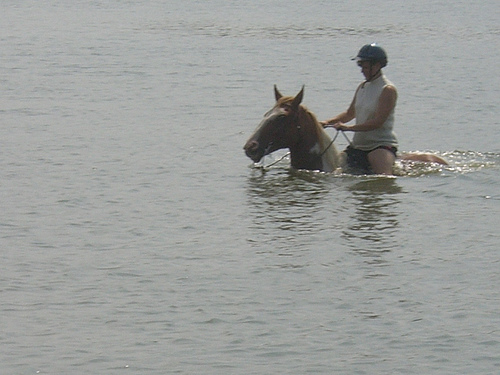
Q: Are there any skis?
A: No, there are no skis.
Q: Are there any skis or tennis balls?
A: No, there are no skis or tennis balls.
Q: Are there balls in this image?
A: No, there are no balls.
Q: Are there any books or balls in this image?
A: No, there are no balls or books.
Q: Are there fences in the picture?
A: No, there are no fences.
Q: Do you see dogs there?
A: No, there are no dogs.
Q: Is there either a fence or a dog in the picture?
A: No, there are no dogs or fences.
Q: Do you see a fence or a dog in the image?
A: No, there are no dogs or fences.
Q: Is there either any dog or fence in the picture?
A: No, there are no dogs or fences.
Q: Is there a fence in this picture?
A: No, there are no fences.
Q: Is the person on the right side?
A: Yes, the person is on the right of the image.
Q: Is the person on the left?
A: No, the person is on the right of the image.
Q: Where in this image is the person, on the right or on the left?
A: The person is on the right of the image.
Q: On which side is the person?
A: The person is on the right of the image.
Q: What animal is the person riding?
A: The person is riding a horse.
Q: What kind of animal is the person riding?
A: The person is riding a horse.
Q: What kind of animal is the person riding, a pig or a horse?
A: The person is riding a horse.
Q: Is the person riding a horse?
A: Yes, the person is riding a horse.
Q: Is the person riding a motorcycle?
A: No, the person is riding a horse.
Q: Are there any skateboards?
A: No, there are no skateboards.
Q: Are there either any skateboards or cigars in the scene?
A: No, there are no skateboards or cigars.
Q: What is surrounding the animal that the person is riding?
A: The water is surrounding the horse.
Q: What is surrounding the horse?
A: The water is surrounding the horse.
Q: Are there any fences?
A: No, there are no fences.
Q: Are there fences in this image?
A: No, there are no fences.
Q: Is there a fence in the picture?
A: No, there are no fences.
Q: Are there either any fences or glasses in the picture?
A: No, there are no fences or glasses.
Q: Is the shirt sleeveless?
A: Yes, the shirt is sleeveless.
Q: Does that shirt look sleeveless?
A: Yes, the shirt is sleeveless.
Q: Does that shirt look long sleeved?
A: No, the shirt is sleeveless.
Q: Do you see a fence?
A: No, there are no fences.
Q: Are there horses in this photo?
A: Yes, there is a horse.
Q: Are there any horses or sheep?
A: Yes, there is a horse.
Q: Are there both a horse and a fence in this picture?
A: No, there is a horse but no fences.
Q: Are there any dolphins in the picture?
A: No, there are no dolphins.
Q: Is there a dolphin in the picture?
A: No, there are no dolphins.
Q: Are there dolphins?
A: No, there are no dolphins.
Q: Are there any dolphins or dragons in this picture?
A: No, there are no dolphins or dragons.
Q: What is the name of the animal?
A: The animal is a horse.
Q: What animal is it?
A: The animal is a horse.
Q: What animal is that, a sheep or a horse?
A: This is a horse.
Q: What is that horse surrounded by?
A: The horse is surrounded by the water.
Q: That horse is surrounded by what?
A: The horse is surrounded by the water.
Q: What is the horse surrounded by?
A: The horse is surrounded by the water.